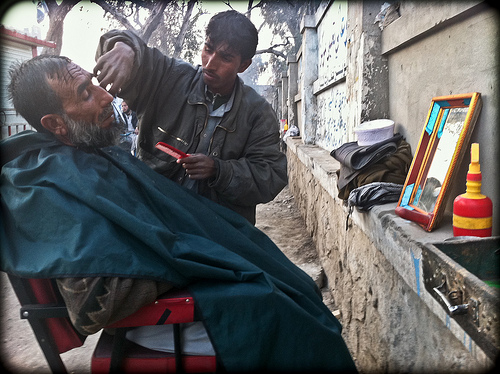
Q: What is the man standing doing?
A: Trimming a beard.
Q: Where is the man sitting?
A: In a chair.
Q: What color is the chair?
A: Red.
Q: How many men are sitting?
A: One.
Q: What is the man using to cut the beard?
A: Scissors.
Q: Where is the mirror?
A: On the ledge.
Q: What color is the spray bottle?
A: Red & yellow.